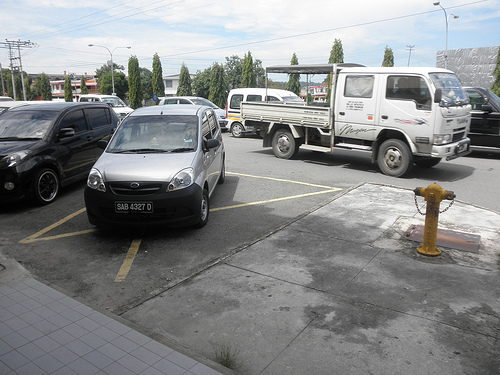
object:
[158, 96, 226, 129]
car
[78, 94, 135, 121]
car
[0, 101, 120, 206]
car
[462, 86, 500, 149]
truck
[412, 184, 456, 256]
hydrant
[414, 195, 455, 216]
chain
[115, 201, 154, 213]
license plate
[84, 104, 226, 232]
car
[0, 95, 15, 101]
car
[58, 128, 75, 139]
mirror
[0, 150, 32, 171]
headlight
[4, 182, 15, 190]
fog light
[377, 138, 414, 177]
tire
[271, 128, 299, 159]
tire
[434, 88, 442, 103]
mirror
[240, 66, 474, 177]
truck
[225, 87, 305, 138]
van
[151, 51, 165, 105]
tree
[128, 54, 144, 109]
tree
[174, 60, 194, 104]
tree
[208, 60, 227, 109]
tree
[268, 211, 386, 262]
mark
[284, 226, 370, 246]
crack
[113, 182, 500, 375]
pavement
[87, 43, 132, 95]
light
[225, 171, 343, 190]
lines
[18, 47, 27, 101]
pole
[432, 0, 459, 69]
street light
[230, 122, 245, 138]
wheel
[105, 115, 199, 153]
glass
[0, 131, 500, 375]
floor